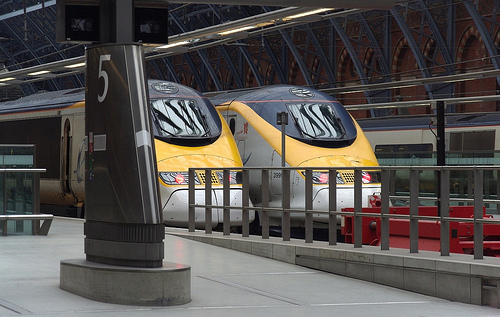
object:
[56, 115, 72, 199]
door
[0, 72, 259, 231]
train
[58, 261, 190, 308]
concrete base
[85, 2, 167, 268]
pole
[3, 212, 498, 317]
concrete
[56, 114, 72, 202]
entrance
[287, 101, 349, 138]
windshield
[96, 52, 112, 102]
sign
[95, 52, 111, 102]
number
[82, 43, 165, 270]
post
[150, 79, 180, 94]
emblem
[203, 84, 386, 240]
train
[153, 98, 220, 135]
windshield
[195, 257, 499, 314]
ground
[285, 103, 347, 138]
reflection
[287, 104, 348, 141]
window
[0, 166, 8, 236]
pole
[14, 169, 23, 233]
pole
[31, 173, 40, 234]
pole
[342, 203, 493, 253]
railing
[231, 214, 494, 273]
track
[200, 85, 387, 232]
rail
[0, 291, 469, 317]
slabs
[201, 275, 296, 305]
lines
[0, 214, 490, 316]
walking area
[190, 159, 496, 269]
metal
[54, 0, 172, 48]
lights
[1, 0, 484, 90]
ceiling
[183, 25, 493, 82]
roof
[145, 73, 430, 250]
light rails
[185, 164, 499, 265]
railing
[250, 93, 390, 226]
end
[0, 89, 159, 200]
side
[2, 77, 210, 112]
top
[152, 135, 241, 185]
paint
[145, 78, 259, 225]
front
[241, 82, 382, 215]
front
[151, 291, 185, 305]
marks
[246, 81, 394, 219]
face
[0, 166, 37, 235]
glass